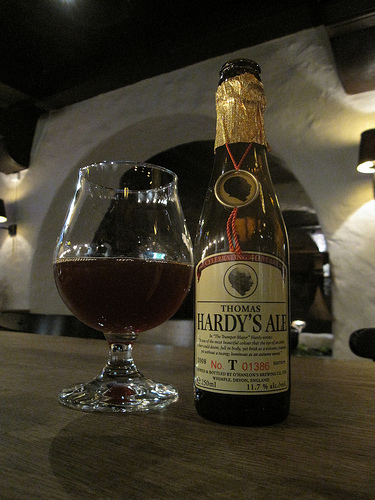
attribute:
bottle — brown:
[199, 151, 283, 420]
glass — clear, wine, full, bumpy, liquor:
[80, 164, 174, 419]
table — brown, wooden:
[1, 385, 58, 423]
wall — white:
[283, 49, 312, 75]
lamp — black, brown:
[355, 121, 373, 164]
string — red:
[226, 146, 238, 161]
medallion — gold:
[216, 173, 260, 212]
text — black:
[208, 313, 235, 346]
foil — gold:
[234, 94, 252, 104]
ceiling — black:
[12, 30, 91, 72]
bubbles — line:
[71, 247, 105, 257]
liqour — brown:
[225, 149, 263, 163]